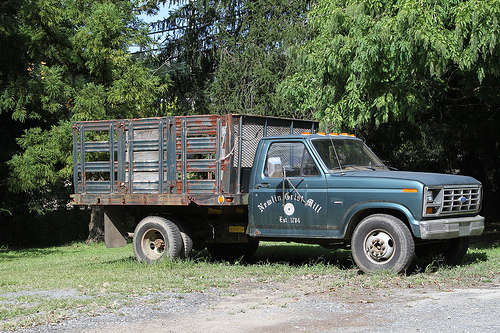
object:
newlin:
[256, 192, 284, 214]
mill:
[304, 198, 322, 216]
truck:
[67, 110, 487, 284]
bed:
[65, 110, 321, 218]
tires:
[131, 213, 416, 280]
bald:
[349, 212, 419, 273]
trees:
[2, 1, 499, 240]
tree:
[2, 0, 140, 243]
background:
[3, 0, 500, 259]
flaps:
[101, 205, 144, 251]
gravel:
[2, 275, 227, 333]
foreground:
[1, 245, 499, 332]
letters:
[315, 205, 323, 215]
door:
[249, 133, 332, 242]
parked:
[71, 112, 487, 287]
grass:
[3, 214, 499, 309]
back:
[70, 112, 320, 214]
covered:
[53, 0, 354, 98]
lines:
[118, 8, 271, 42]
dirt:
[135, 273, 499, 332]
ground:
[1, 218, 499, 329]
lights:
[302, 129, 359, 141]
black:
[369, 222, 382, 229]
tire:
[349, 212, 418, 279]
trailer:
[68, 112, 321, 212]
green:
[349, 179, 388, 188]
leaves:
[1, 0, 499, 214]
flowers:
[32, 74, 50, 85]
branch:
[7, 42, 81, 102]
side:
[265, 154, 309, 210]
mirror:
[265, 154, 287, 181]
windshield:
[307, 131, 392, 179]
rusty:
[167, 114, 234, 208]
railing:
[172, 117, 235, 137]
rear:
[67, 116, 249, 269]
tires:
[130, 213, 197, 270]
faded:
[104, 207, 130, 252]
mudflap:
[99, 209, 131, 252]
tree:
[275, 2, 499, 201]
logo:
[456, 196, 470, 205]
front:
[222, 114, 320, 209]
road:
[4, 267, 498, 333]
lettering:
[255, 202, 264, 213]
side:
[247, 133, 340, 239]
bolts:
[366, 245, 380, 255]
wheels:
[130, 211, 417, 280]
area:
[1, 278, 499, 333]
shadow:
[183, 238, 490, 275]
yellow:
[302, 131, 312, 136]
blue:
[457, 195, 467, 206]